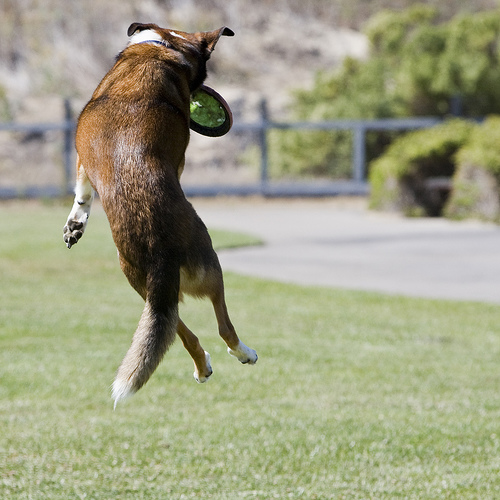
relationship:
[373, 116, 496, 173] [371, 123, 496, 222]
weeds are on rocks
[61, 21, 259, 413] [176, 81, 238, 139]
dog catching frisbee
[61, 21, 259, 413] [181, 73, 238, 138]
dog catching frisbee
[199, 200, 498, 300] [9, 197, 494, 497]
driveway covering ground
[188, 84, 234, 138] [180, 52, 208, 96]
frisbee in dog's mouth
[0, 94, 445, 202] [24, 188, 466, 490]
fence on property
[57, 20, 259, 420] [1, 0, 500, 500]
dog playing in park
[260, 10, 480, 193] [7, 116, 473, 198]
tree behind fence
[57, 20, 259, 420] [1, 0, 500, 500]
dog exercising in park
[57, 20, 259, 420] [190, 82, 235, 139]
dog has a frisbee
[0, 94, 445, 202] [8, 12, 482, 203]
fence in background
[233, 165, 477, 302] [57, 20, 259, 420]
walkway near dog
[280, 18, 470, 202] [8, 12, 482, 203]
trees are in background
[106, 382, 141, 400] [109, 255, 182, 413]
tip of tail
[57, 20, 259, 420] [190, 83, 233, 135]
dog catching a frisbee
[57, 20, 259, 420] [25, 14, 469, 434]
dog jumping in air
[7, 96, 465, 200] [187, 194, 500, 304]
fence at end of a walkway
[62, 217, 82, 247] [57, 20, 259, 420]
paw of a dog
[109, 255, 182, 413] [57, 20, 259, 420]
tail of a dog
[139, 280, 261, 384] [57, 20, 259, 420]
legs of a jumping dog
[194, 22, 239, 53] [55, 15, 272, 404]
ear of a dog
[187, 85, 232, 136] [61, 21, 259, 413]
frisbee in mouth of dog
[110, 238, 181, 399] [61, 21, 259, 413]
tail on back of dog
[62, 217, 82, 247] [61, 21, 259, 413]
paw on dog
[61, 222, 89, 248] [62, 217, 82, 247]
pad on paw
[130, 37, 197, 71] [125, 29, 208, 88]
collar on neck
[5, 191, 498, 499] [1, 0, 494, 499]
grass in park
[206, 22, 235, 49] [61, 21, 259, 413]
ear of dog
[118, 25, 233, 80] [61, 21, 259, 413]
head of dog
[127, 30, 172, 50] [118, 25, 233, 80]
patch on head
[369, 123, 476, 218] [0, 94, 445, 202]
bush in front of fence